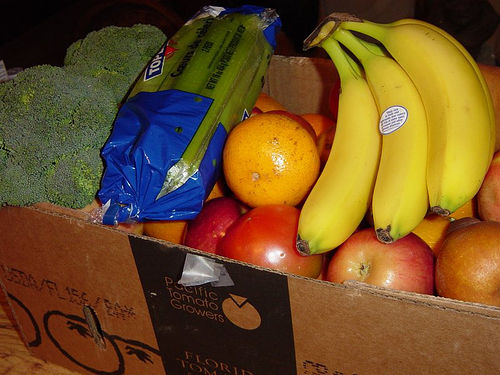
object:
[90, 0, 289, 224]
bag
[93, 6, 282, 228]
celery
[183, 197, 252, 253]
apple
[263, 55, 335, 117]
box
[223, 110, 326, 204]
orange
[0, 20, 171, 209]
broccoli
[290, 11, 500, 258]
bananas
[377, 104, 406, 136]
stickers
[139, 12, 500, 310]
fruit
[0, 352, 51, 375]
floor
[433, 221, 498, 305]
pear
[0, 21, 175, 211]
boccoli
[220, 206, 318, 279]
tomato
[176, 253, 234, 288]
tape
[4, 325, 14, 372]
wooden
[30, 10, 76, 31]
dark background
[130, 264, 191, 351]
patch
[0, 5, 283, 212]
vegetables